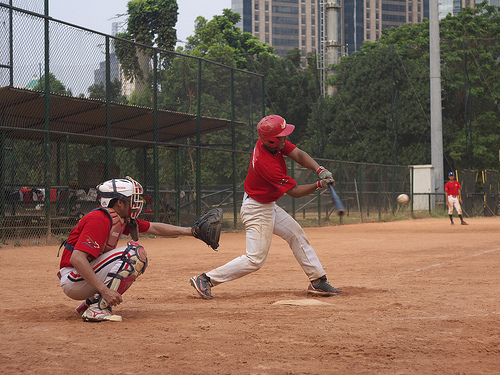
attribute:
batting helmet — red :
[251, 110, 296, 148]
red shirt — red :
[236, 131, 306, 210]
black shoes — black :
[305, 272, 354, 315]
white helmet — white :
[87, 174, 148, 218]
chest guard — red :
[98, 204, 143, 275]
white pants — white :
[46, 235, 143, 321]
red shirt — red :
[65, 197, 141, 269]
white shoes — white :
[75, 292, 127, 323]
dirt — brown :
[349, 221, 469, 362]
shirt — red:
[247, 139, 297, 203]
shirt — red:
[444, 180, 464, 191]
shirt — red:
[241, 138, 291, 203]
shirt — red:
[248, 139, 294, 198]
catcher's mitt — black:
[194, 208, 222, 247]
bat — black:
[328, 181, 344, 220]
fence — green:
[4, 2, 409, 232]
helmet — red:
[257, 113, 297, 152]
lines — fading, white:
[394, 246, 484, 311]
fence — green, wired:
[5, 8, 477, 235]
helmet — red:
[259, 113, 294, 144]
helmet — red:
[253, 104, 294, 142]